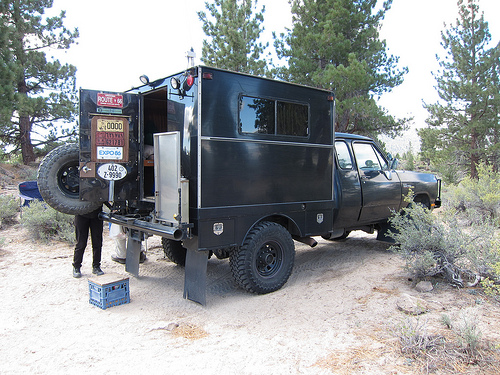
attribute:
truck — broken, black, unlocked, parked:
[78, 65, 441, 296]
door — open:
[78, 86, 143, 204]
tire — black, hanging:
[35, 142, 100, 216]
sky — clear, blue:
[77, 1, 182, 69]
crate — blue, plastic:
[87, 270, 134, 310]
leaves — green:
[429, 69, 441, 77]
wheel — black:
[232, 218, 297, 295]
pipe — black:
[97, 210, 181, 241]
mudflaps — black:
[122, 229, 213, 309]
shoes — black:
[70, 264, 106, 277]